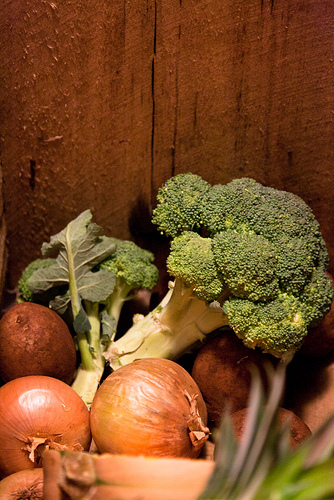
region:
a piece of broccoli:
[116, 172, 330, 374]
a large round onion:
[91, 362, 212, 457]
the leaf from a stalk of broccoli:
[28, 210, 112, 357]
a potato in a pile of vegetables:
[4, 300, 77, 376]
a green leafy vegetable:
[214, 363, 285, 496]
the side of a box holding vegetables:
[3, 65, 329, 186]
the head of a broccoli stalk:
[153, 194, 329, 345]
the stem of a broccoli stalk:
[105, 301, 214, 363]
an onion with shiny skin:
[0, 373, 88, 459]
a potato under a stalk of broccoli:
[198, 335, 256, 413]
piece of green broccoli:
[13, 203, 151, 407]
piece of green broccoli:
[99, 171, 332, 380]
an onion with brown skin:
[83, 350, 210, 464]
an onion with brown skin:
[0, 373, 97, 476]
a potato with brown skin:
[0, 297, 81, 382]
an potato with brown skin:
[186, 332, 269, 422]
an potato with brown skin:
[217, 401, 309, 453]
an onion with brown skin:
[0, 459, 52, 498]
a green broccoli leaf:
[25, 208, 117, 365]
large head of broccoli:
[95, 168, 329, 378]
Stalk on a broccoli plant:
[110, 293, 203, 367]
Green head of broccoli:
[158, 171, 328, 354]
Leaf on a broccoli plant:
[42, 221, 106, 317]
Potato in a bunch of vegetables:
[2, 302, 78, 381]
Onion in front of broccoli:
[89, 365, 207, 456]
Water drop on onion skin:
[61, 402, 69, 411]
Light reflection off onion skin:
[12, 384, 57, 411]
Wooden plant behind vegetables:
[167, 4, 326, 216]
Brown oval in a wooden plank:
[27, 157, 37, 189]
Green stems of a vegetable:
[210, 362, 293, 498]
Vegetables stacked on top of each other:
[1, 168, 332, 498]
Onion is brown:
[93, 355, 207, 459]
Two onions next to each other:
[0, 360, 213, 472]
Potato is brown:
[0, 300, 82, 378]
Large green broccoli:
[94, 172, 333, 365]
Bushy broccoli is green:
[99, 174, 330, 367]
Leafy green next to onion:
[27, 207, 115, 410]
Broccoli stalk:
[95, 273, 239, 373]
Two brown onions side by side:
[3, 351, 223, 474]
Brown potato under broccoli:
[189, 339, 272, 422]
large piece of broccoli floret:
[157, 155, 311, 335]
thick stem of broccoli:
[114, 288, 161, 397]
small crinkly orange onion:
[75, 350, 202, 450]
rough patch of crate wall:
[13, 58, 102, 208]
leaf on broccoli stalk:
[28, 228, 109, 354]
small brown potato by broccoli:
[5, 274, 79, 388]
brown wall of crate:
[35, 132, 140, 195]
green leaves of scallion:
[227, 389, 330, 492]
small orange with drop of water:
[0, 368, 96, 480]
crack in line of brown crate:
[147, 10, 173, 177]